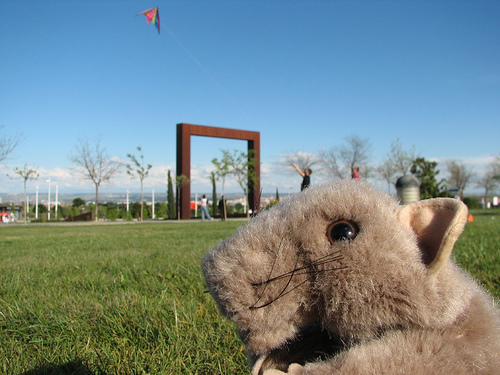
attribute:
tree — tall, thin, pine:
[166, 167, 176, 221]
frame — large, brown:
[175, 120, 262, 217]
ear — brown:
[403, 197, 467, 275]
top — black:
[297, 169, 312, 190]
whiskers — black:
[243, 232, 355, 313]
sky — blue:
[0, 2, 498, 193]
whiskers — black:
[244, 240, 346, 313]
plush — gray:
[203, 177, 498, 373]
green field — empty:
[0, 205, 500, 374]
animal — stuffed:
[252, 174, 426, 315]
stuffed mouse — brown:
[189, 173, 493, 373]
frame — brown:
[171, 118, 265, 221]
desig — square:
[175, 122, 262, 214]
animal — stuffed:
[195, 181, 489, 373]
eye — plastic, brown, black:
[323, 214, 371, 244]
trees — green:
[89, 193, 166, 223]